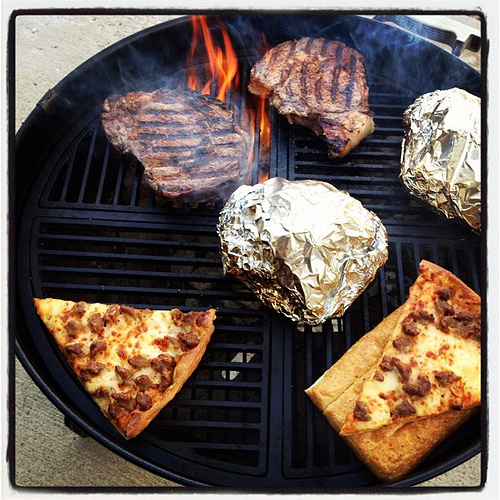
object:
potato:
[216, 175, 389, 325]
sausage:
[180, 327, 201, 346]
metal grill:
[255, 134, 333, 185]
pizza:
[31, 293, 219, 443]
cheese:
[119, 325, 154, 368]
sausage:
[171, 327, 201, 351]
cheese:
[423, 330, 484, 391]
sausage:
[433, 288, 475, 331]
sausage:
[61, 302, 94, 341]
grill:
[17, 15, 487, 490]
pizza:
[338, 260, 485, 437]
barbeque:
[96, 80, 257, 201]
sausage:
[402, 320, 419, 337]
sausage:
[403, 381, 435, 395]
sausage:
[388, 400, 417, 417]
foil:
[403, 74, 483, 252]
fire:
[183, 14, 245, 106]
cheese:
[154, 311, 168, 332]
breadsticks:
[27, 295, 215, 441]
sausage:
[375, 355, 418, 377]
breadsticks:
[305, 258, 482, 478]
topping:
[88, 339, 110, 354]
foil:
[217, 176, 387, 325]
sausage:
[124, 351, 153, 371]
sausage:
[87, 344, 106, 362]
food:
[250, 35, 376, 167]